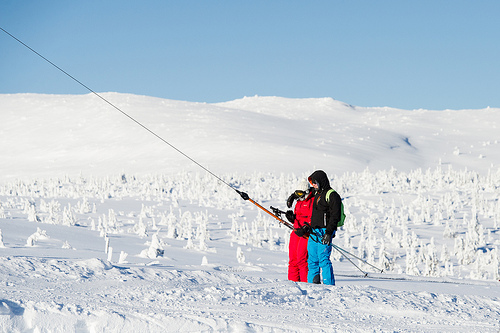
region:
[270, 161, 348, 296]
people standing in white snow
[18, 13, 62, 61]
white clouds in blue sky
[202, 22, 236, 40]
white clouds in blue sky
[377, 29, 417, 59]
white clouds in blue sky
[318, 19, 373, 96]
white clouds in blue sky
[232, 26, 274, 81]
white clouds in blue sky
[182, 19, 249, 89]
white clouds in blue sky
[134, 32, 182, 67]
white clouds in blue sky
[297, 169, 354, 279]
A man standing on snow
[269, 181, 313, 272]
A man standing on snow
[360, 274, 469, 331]
A ground covered by snow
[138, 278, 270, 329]
A ground covered by snow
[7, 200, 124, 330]
A ground covered by snow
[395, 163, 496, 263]
A ground covered by snow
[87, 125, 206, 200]
A ground covered by snow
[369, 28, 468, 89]
A blue sky cover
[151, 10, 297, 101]
A blue sky cover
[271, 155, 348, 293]
skiers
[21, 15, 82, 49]
white clouds in blue sky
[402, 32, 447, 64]
white clouds in blue sky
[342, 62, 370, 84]
white clouds in blue sky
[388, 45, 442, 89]
white clouds in blue sky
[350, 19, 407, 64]
white clouds in blue sky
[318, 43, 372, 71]
white clouds in blue sky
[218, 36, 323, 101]
white clouds in blue sky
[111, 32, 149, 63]
white clouds in blue sky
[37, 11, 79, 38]
white clouds in blue sky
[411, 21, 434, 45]
white clouds in blue sky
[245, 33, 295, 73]
white clouds in blue sky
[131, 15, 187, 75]
white clouds in blue sky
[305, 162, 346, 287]
person standing in the snow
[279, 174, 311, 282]
person standing in the snow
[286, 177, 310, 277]
person wearing all red jumpsuit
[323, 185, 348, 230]
green backpack on person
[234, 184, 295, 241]
red and black pole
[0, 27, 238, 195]
thin jet black string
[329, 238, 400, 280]
two ski poles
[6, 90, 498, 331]
a large white snowy terrain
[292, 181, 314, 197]
white and yellow helmet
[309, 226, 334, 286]
bright blue pants on person